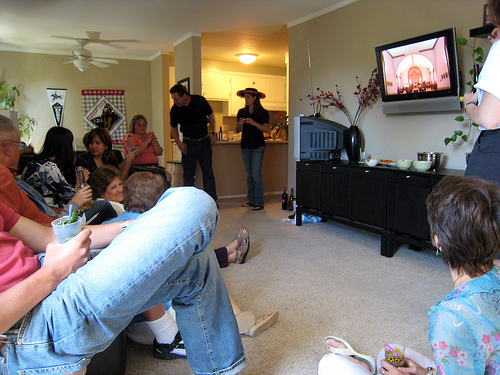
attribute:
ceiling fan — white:
[48, 44, 114, 72]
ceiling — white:
[44, 42, 120, 77]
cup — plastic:
[49, 212, 84, 247]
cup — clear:
[382, 340, 407, 367]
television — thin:
[366, 29, 487, 112]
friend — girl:
[233, 87, 277, 214]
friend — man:
[162, 76, 219, 204]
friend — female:
[124, 114, 162, 175]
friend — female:
[66, 122, 126, 188]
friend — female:
[318, 175, 498, 374]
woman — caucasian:
[237, 86, 272, 211]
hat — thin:
[229, 82, 271, 106]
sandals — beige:
[235, 179, 282, 269]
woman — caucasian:
[302, 166, 493, 368]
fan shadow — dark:
[53, 32, 140, 52]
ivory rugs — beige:
[125, 200, 447, 373]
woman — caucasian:
[317, 177, 497, 374]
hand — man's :
[42, 226, 91, 279]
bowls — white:
[394, 152, 450, 189]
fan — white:
[45, 40, 117, 77]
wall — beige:
[283, 5, 499, 242]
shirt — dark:
[220, 103, 287, 148]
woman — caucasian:
[211, 63, 333, 216]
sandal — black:
[187, 264, 301, 344]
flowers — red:
[298, 67, 384, 124]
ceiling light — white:
[223, 37, 264, 72]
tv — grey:
[293, 113, 351, 165]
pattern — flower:
[438, 294, 484, 363]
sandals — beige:
[233, 223, 251, 264]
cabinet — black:
[295, 159, 429, 255]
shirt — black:
[236, 106, 270, 146]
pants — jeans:
[240, 140, 268, 206]